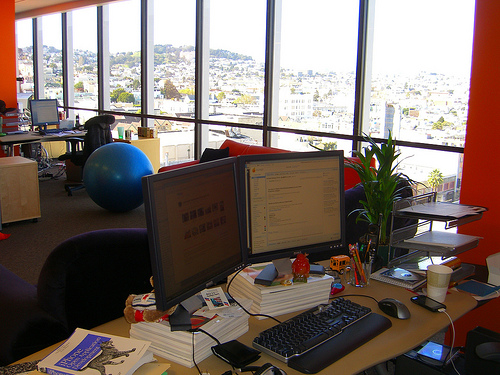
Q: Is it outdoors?
A: Yes, it is outdoors.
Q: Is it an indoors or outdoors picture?
A: It is outdoors.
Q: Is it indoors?
A: No, it is outdoors.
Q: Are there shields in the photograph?
A: No, there are no shields.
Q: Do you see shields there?
A: No, there are no shields.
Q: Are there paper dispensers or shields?
A: No, there are no shields or paper dispensers.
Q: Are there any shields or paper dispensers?
A: No, there are no shields or paper dispensers.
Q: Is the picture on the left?
A: Yes, the picture is on the left of the image.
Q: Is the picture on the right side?
A: No, the picture is on the left of the image.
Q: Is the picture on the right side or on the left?
A: The picture is on the left of the image.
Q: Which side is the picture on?
A: The picture is on the left of the image.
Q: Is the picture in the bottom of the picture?
A: Yes, the picture is in the bottom of the image.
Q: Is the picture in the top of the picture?
A: No, the picture is in the bottom of the image.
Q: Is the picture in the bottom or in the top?
A: The picture is in the bottom of the image.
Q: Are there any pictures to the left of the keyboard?
A: Yes, there is a picture to the left of the keyboard.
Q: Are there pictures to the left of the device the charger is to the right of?
A: Yes, there is a picture to the left of the keyboard.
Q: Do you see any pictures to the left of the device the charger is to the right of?
A: Yes, there is a picture to the left of the keyboard.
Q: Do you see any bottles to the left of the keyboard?
A: No, there is a picture to the left of the keyboard.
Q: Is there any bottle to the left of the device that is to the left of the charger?
A: No, there is a picture to the left of the keyboard.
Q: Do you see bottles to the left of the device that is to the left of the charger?
A: No, there is a picture to the left of the keyboard.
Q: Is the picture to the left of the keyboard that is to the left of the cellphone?
A: Yes, the picture is to the left of the keyboard.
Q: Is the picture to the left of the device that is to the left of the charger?
A: Yes, the picture is to the left of the keyboard.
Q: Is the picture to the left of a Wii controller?
A: No, the picture is to the left of the keyboard.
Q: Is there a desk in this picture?
A: Yes, there is a desk.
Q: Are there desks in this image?
A: Yes, there is a desk.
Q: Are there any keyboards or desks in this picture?
A: Yes, there is a desk.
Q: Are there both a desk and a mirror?
A: No, there is a desk but no mirrors.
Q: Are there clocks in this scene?
A: No, there are no clocks.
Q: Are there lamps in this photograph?
A: No, there are no lamps.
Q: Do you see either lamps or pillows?
A: No, there are no lamps or pillows.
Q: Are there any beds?
A: No, there are no beds.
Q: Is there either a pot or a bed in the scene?
A: No, there are no beds or pots.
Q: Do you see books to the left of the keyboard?
A: Yes, there is a book to the left of the keyboard.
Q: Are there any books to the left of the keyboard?
A: Yes, there is a book to the left of the keyboard.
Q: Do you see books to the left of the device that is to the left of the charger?
A: Yes, there is a book to the left of the keyboard.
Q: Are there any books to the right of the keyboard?
A: No, the book is to the left of the keyboard.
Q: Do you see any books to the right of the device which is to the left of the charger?
A: No, the book is to the left of the keyboard.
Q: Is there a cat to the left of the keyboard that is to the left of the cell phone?
A: No, there is a book to the left of the keyboard.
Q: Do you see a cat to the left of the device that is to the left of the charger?
A: No, there is a book to the left of the keyboard.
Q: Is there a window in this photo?
A: Yes, there is a window.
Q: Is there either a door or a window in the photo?
A: Yes, there is a window.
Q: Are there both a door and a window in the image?
A: No, there is a window but no doors.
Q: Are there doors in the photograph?
A: No, there are no doors.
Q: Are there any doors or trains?
A: No, there are no doors or trains.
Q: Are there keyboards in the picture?
A: Yes, there is a keyboard.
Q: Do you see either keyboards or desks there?
A: Yes, there is a keyboard.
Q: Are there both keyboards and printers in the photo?
A: No, there is a keyboard but no printers.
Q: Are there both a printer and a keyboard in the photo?
A: No, there is a keyboard but no printers.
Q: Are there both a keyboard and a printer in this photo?
A: No, there is a keyboard but no printers.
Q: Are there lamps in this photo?
A: No, there are no lamps.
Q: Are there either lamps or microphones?
A: No, there are no lamps or microphones.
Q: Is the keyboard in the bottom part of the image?
A: Yes, the keyboard is in the bottom of the image.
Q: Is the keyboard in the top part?
A: No, the keyboard is in the bottom of the image.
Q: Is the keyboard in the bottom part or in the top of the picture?
A: The keyboard is in the bottom of the image.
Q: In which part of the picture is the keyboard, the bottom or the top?
A: The keyboard is in the bottom of the image.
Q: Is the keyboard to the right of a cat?
A: No, the keyboard is to the right of the book.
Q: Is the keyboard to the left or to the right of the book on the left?
A: The keyboard is to the right of the book.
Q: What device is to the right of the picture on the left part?
A: The device is a keyboard.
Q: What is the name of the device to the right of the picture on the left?
A: The device is a keyboard.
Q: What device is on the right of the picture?
A: The device is a keyboard.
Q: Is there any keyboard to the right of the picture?
A: Yes, there is a keyboard to the right of the picture.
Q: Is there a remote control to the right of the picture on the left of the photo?
A: No, there is a keyboard to the right of the picture.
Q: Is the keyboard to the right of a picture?
A: Yes, the keyboard is to the right of a picture.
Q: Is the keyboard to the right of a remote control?
A: No, the keyboard is to the right of a picture.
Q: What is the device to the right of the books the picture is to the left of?
A: The device is a keyboard.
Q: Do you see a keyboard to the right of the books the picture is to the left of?
A: Yes, there is a keyboard to the right of the books.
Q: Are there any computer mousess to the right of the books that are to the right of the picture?
A: No, there is a keyboard to the right of the books.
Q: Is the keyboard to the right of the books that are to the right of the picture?
A: Yes, the keyboard is to the right of the books.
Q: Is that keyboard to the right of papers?
A: No, the keyboard is to the right of the books.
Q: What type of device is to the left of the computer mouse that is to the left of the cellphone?
A: The device is a keyboard.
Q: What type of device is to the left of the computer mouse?
A: The device is a keyboard.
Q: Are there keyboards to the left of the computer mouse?
A: Yes, there is a keyboard to the left of the computer mouse.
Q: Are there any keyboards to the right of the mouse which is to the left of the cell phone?
A: No, the keyboard is to the left of the mouse.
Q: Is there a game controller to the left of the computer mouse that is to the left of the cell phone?
A: No, there is a keyboard to the left of the computer mouse.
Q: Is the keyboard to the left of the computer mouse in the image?
A: Yes, the keyboard is to the left of the computer mouse.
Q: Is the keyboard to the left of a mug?
A: No, the keyboard is to the left of the computer mouse.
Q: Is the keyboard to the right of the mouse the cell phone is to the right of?
A: No, the keyboard is to the left of the computer mouse.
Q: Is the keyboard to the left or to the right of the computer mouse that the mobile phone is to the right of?
A: The keyboard is to the left of the mouse.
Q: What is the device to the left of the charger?
A: The device is a keyboard.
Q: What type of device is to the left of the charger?
A: The device is a keyboard.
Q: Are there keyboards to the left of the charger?
A: Yes, there is a keyboard to the left of the charger.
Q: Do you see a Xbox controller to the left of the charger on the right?
A: No, there is a keyboard to the left of the charger.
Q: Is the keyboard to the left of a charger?
A: Yes, the keyboard is to the left of a charger.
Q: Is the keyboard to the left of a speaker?
A: No, the keyboard is to the left of a charger.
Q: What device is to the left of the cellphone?
A: The device is a keyboard.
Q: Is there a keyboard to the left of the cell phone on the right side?
A: Yes, there is a keyboard to the left of the mobile phone.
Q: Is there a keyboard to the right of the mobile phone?
A: No, the keyboard is to the left of the mobile phone.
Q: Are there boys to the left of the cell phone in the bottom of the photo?
A: No, there is a keyboard to the left of the mobile phone.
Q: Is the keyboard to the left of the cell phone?
A: Yes, the keyboard is to the left of the cell phone.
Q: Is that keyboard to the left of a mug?
A: No, the keyboard is to the left of the cell phone.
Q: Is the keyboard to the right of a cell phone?
A: No, the keyboard is to the left of a cell phone.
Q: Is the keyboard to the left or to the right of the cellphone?
A: The keyboard is to the left of the cellphone.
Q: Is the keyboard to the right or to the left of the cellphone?
A: The keyboard is to the left of the cellphone.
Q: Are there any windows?
A: Yes, there are windows.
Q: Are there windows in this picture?
A: Yes, there are windows.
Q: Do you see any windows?
A: Yes, there are windows.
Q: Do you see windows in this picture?
A: Yes, there are windows.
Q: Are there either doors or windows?
A: Yes, there are windows.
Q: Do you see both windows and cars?
A: No, there are windows but no cars.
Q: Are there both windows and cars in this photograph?
A: No, there are windows but no cars.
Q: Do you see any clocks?
A: No, there are no clocks.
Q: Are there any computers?
A: Yes, there is a computer.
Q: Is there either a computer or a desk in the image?
A: Yes, there is a computer.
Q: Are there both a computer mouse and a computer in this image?
A: Yes, there are both a computer and a computer mouse.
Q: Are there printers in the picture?
A: No, there are no printers.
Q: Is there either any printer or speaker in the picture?
A: No, there are no printers or speakers.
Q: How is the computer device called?
A: The device is a computer.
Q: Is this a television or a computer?
A: This is a computer.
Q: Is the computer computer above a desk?
A: Yes, the computer is above a desk.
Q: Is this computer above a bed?
A: No, the computer is above a desk.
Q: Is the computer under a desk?
A: No, the computer is above a desk.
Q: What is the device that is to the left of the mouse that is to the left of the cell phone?
A: The device is a computer.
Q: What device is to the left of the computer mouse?
A: The device is a computer.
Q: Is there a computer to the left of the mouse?
A: Yes, there is a computer to the left of the mouse.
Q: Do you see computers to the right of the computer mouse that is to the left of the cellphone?
A: No, the computer is to the left of the mouse.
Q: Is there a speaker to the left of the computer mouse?
A: No, there is a computer to the left of the computer mouse.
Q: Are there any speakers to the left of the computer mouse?
A: No, there is a computer to the left of the computer mouse.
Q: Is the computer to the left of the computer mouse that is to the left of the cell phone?
A: Yes, the computer is to the left of the computer mouse.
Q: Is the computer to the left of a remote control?
A: No, the computer is to the left of the computer mouse.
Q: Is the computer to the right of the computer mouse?
A: No, the computer is to the left of the computer mouse.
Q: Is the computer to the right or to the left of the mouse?
A: The computer is to the left of the mouse.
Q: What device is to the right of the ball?
A: The device is a computer.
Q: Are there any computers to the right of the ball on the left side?
A: Yes, there is a computer to the right of the ball.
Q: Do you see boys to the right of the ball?
A: No, there is a computer to the right of the ball.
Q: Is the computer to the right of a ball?
A: Yes, the computer is to the right of a ball.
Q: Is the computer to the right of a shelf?
A: No, the computer is to the right of a ball.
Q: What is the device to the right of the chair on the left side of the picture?
A: The device is a computer.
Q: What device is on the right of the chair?
A: The device is a computer.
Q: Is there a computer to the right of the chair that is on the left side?
A: Yes, there is a computer to the right of the chair.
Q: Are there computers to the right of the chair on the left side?
A: Yes, there is a computer to the right of the chair.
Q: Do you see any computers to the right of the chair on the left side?
A: Yes, there is a computer to the right of the chair.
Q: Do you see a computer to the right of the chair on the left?
A: Yes, there is a computer to the right of the chair.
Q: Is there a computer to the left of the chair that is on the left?
A: No, the computer is to the right of the chair.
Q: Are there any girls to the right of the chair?
A: No, there is a computer to the right of the chair.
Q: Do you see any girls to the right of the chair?
A: No, there is a computer to the right of the chair.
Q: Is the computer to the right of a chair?
A: Yes, the computer is to the right of a chair.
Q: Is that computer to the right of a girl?
A: No, the computer is to the right of a chair.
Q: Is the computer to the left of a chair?
A: No, the computer is to the right of a chair.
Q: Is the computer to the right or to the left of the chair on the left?
A: The computer is to the right of the chair.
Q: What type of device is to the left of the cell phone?
A: The device is a computer.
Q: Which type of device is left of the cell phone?
A: The device is a computer.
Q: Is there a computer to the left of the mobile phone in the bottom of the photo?
A: Yes, there is a computer to the left of the mobile phone.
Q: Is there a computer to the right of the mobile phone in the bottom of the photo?
A: No, the computer is to the left of the cell phone.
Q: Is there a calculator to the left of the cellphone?
A: No, there is a computer to the left of the cellphone.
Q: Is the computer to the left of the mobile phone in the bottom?
A: Yes, the computer is to the left of the cell phone.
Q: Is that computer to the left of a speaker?
A: No, the computer is to the left of the cell phone.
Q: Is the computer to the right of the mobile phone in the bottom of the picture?
A: No, the computer is to the left of the mobile phone.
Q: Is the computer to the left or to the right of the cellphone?
A: The computer is to the left of the cellphone.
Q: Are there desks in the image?
A: Yes, there is a desk.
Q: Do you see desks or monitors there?
A: Yes, there is a desk.